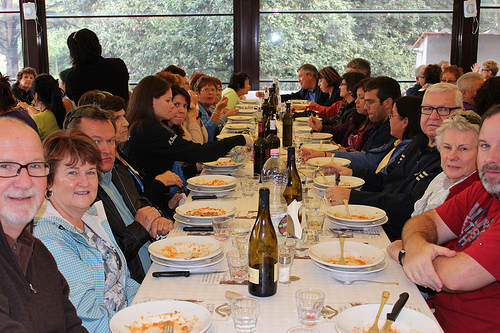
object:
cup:
[294, 288, 326, 326]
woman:
[120, 76, 255, 217]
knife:
[381, 291, 408, 332]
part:
[384, 312, 396, 321]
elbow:
[438, 276, 474, 294]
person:
[308, 71, 377, 152]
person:
[195, 75, 229, 143]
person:
[62, 105, 173, 284]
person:
[158, 85, 193, 142]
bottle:
[247, 186, 279, 299]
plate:
[307, 238, 390, 283]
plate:
[185, 174, 239, 196]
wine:
[247, 187, 280, 298]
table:
[122, 100, 444, 333]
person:
[408, 109, 485, 220]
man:
[386, 102, 499, 333]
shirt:
[432, 181, 498, 333]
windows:
[2, 0, 499, 101]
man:
[0, 115, 93, 333]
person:
[192, 75, 239, 143]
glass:
[229, 297, 259, 333]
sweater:
[1, 230, 87, 333]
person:
[359, 75, 403, 152]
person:
[29, 128, 141, 332]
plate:
[311, 175, 366, 198]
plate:
[173, 201, 238, 228]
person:
[324, 82, 466, 241]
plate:
[332, 304, 441, 333]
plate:
[106, 300, 214, 333]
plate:
[146, 235, 225, 271]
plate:
[326, 204, 386, 230]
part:
[259, 287, 269, 293]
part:
[444, 254, 469, 279]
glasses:
[0, 161, 53, 179]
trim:
[238, 1, 261, 90]